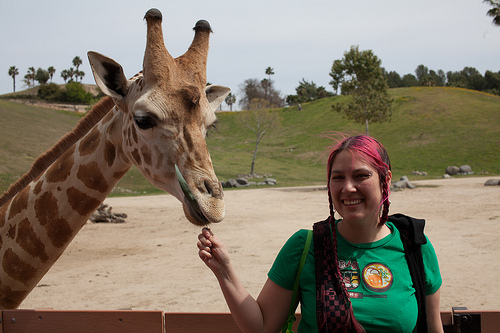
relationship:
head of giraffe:
[85, 7, 231, 228] [0, 7, 232, 310]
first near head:
[198, 226, 232, 273] [85, 7, 231, 228]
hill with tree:
[0, 82, 500, 196] [330, 48, 393, 136]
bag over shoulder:
[311, 216, 352, 332] [277, 224, 435, 289]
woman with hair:
[197, 129, 445, 332] [320, 128, 394, 331]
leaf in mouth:
[172, 163, 210, 222] [180, 191, 227, 226]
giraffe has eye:
[0, 7, 232, 310] [133, 111, 157, 132]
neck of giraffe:
[0, 97, 133, 309] [0, 7, 232, 310]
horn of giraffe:
[143, 7, 176, 76] [0, 7, 232, 310]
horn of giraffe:
[175, 18, 211, 84] [0, 7, 232, 310]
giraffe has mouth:
[0, 7, 232, 310] [180, 191, 227, 226]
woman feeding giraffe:
[197, 129, 445, 332] [0, 7, 232, 310]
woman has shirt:
[197, 129, 445, 332] [267, 218, 442, 332]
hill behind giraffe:
[0, 82, 500, 196] [0, 7, 232, 310]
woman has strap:
[197, 129, 445, 332] [284, 229, 315, 333]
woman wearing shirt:
[197, 129, 445, 332] [267, 218, 442, 332]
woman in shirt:
[197, 129, 445, 332] [267, 218, 442, 332]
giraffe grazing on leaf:
[0, 7, 232, 310] [172, 163, 210, 222]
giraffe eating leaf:
[0, 7, 232, 310] [172, 163, 210, 222]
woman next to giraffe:
[197, 129, 445, 332] [0, 7, 232, 310]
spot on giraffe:
[75, 158, 111, 193] [0, 7, 232, 310]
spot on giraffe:
[44, 142, 77, 183] [0, 7, 232, 310]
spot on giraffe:
[78, 124, 103, 157] [0, 7, 232, 310]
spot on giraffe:
[65, 184, 102, 216] [0, 7, 232, 310]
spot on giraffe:
[33, 191, 75, 250] [0, 7, 232, 310]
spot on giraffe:
[15, 217, 50, 263] [0, 7, 232, 310]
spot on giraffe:
[1, 246, 38, 287] [0, 7, 232, 310]